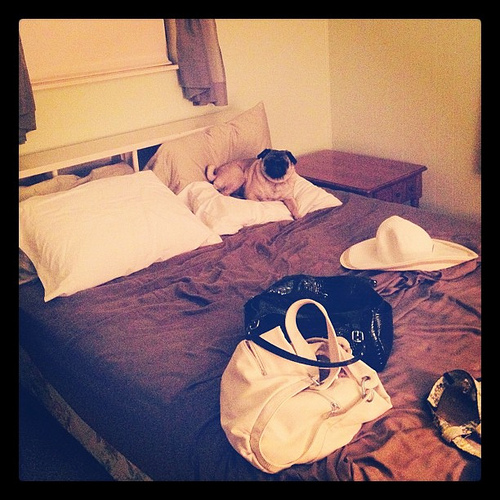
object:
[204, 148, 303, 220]
pug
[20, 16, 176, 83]
window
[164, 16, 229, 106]
curtain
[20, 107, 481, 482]
bed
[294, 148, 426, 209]
table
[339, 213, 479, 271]
hat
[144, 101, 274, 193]
pillow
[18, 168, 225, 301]
pillows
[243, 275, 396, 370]
purse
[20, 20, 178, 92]
shades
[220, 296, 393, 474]
bags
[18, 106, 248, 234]
bookshelf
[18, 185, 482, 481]
blanket